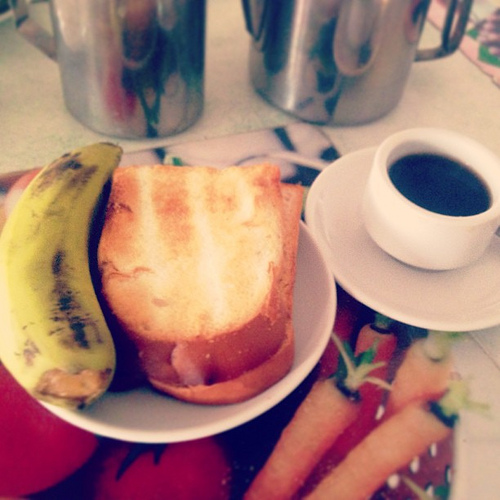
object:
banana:
[1, 139, 122, 414]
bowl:
[10, 176, 337, 444]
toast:
[94, 162, 289, 386]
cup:
[362, 125, 499, 273]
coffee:
[388, 149, 495, 217]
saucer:
[300, 145, 499, 335]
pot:
[239, 0, 470, 125]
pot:
[8, 1, 209, 142]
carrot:
[299, 401, 461, 498]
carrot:
[241, 371, 362, 500]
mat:
[1, 120, 500, 499]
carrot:
[381, 330, 450, 430]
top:
[332, 333, 395, 394]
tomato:
[93, 434, 234, 499]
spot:
[47, 248, 101, 351]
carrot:
[329, 325, 393, 469]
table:
[0, 0, 500, 500]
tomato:
[0, 361, 99, 496]